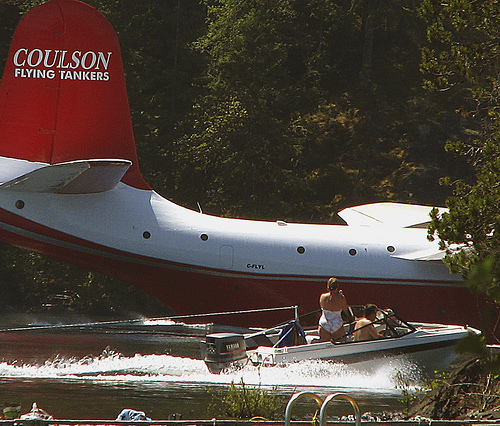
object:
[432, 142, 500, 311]
branches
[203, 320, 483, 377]
motorboat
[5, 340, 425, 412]
splash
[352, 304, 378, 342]
man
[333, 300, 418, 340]
windshield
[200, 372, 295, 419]
bush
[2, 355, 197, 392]
lake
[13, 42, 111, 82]
logo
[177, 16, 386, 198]
tree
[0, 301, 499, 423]
river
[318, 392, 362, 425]
handle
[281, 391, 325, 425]
handle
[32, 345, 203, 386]
water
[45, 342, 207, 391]
wake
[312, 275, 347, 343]
woman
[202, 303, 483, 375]
boat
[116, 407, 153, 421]
clothing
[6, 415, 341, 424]
pier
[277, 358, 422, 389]
water spray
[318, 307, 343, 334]
bathing suit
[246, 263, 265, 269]
letters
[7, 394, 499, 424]
pier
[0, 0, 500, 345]
airplane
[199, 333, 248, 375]
engine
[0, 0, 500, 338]
plane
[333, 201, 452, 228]
wing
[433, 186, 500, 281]
green leaves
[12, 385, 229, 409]
lake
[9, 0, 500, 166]
background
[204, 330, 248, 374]
black engine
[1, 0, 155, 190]
tail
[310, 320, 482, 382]
stripe